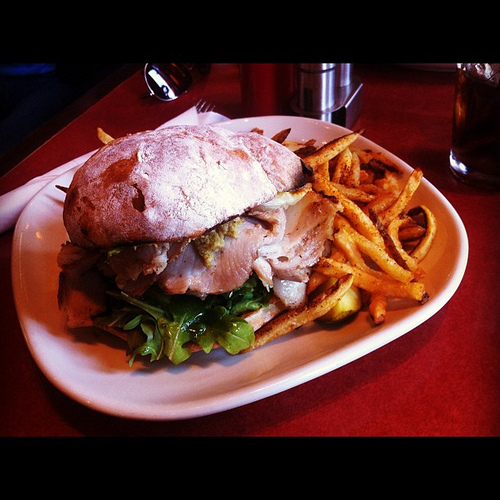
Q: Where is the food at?
A: White plate.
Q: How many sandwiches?
A: One.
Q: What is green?
A: Lettuce.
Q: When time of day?
A: Daytime.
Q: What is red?
A: Table.